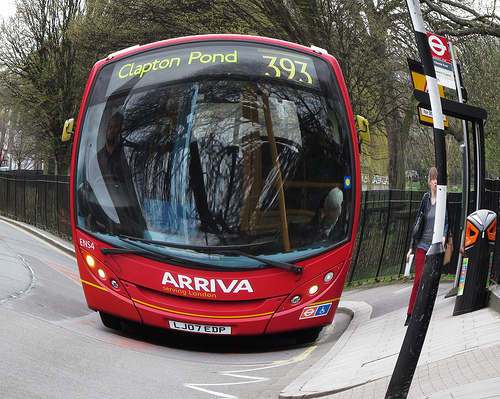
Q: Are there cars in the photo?
A: No, there are no cars.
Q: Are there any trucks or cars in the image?
A: No, there are no cars or trucks.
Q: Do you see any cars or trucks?
A: No, there are no cars or trucks.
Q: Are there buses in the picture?
A: Yes, there is a bus.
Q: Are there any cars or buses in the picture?
A: Yes, there is a bus.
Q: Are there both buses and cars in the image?
A: No, there is a bus but no cars.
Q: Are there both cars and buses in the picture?
A: No, there is a bus but no cars.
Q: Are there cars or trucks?
A: No, there are no cars or trucks.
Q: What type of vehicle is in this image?
A: The vehicle is a bus.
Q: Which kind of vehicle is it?
A: The vehicle is a bus.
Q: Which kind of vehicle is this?
A: That is a bus.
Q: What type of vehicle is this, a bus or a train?
A: That is a bus.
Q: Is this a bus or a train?
A: This is a bus.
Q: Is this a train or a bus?
A: This is a bus.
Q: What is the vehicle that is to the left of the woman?
A: The vehicle is a bus.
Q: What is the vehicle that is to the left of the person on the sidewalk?
A: The vehicle is a bus.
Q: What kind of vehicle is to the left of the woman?
A: The vehicle is a bus.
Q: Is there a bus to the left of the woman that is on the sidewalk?
A: Yes, there is a bus to the left of the woman.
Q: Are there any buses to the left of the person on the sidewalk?
A: Yes, there is a bus to the left of the woman.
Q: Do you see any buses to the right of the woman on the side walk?
A: No, the bus is to the left of the woman.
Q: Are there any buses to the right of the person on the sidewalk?
A: No, the bus is to the left of the woman.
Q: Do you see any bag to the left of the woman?
A: No, there is a bus to the left of the woman.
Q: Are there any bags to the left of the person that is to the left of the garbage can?
A: No, there is a bus to the left of the woman.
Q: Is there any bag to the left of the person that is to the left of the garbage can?
A: No, there is a bus to the left of the woman.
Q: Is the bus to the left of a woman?
A: Yes, the bus is to the left of a woman.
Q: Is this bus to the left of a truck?
A: No, the bus is to the left of a woman.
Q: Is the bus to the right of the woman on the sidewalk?
A: No, the bus is to the left of the woman.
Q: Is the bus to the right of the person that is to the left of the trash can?
A: No, the bus is to the left of the woman.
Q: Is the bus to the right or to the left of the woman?
A: The bus is to the left of the woman.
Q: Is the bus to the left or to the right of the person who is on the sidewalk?
A: The bus is to the left of the woman.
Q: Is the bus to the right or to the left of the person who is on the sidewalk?
A: The bus is to the left of the woman.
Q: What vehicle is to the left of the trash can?
A: The vehicle is a bus.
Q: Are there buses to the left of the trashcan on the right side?
A: Yes, there is a bus to the left of the garbage can.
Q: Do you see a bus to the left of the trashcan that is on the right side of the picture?
A: Yes, there is a bus to the left of the garbage can.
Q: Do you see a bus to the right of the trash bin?
A: No, the bus is to the left of the trash bin.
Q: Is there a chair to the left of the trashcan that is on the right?
A: No, there is a bus to the left of the trash can.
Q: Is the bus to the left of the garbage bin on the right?
A: Yes, the bus is to the left of the trash bin.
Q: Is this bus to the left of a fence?
A: No, the bus is to the left of the trash bin.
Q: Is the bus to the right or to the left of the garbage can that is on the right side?
A: The bus is to the left of the garbage bin.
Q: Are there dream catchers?
A: No, there are no dream catchers.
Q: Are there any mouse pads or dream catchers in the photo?
A: No, there are no dream catchers or mouse pads.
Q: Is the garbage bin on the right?
A: Yes, the garbage bin is on the right of the image.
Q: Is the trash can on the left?
A: No, the trash can is on the right of the image.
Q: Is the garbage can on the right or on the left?
A: The garbage can is on the right of the image.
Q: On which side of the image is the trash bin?
A: The trash bin is on the right of the image.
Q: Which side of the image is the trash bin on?
A: The trash bin is on the right of the image.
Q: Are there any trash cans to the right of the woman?
A: Yes, there is a trash can to the right of the woman.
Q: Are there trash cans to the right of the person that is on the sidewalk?
A: Yes, there is a trash can to the right of the woman.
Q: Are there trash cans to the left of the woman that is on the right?
A: No, the trash can is to the right of the woman.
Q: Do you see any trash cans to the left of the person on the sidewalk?
A: No, the trash can is to the right of the woman.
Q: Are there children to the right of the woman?
A: No, there is a trash can to the right of the woman.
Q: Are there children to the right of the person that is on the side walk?
A: No, there is a trash can to the right of the woman.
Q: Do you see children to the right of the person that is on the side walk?
A: No, there is a trash can to the right of the woman.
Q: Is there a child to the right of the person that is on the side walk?
A: No, there is a trash can to the right of the woman.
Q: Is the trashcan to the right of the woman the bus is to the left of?
A: Yes, the trashcan is to the right of the woman.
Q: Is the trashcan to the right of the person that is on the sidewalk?
A: Yes, the trashcan is to the right of the woman.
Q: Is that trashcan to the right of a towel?
A: No, the trashcan is to the right of the woman.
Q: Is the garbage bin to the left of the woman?
A: No, the garbage bin is to the right of the woman.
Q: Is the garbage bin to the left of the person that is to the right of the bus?
A: No, the garbage bin is to the right of the woman.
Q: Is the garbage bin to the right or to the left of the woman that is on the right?
A: The garbage bin is to the right of the woman.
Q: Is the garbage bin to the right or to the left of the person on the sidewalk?
A: The garbage bin is to the right of the woman.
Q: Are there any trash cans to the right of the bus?
A: Yes, there is a trash can to the right of the bus.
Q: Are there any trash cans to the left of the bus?
A: No, the trash can is to the right of the bus.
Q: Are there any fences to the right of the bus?
A: No, there is a trash can to the right of the bus.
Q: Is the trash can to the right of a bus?
A: Yes, the trash can is to the right of a bus.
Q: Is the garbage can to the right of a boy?
A: No, the garbage can is to the right of a bus.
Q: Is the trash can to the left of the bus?
A: No, the trash can is to the right of the bus.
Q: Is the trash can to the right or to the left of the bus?
A: The trash can is to the right of the bus.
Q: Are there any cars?
A: No, there are no cars.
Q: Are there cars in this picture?
A: No, there are no cars.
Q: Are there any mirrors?
A: Yes, there is a mirror.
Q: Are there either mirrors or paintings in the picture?
A: Yes, there is a mirror.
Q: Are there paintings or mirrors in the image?
A: Yes, there is a mirror.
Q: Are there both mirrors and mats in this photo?
A: No, there is a mirror but no mats.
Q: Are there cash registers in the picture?
A: No, there are no cash registers.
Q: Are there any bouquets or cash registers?
A: No, there are no cash registers or bouquets.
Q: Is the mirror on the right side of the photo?
A: Yes, the mirror is on the right of the image.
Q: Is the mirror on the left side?
A: No, the mirror is on the right of the image.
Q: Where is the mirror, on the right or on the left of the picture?
A: The mirror is on the right of the image.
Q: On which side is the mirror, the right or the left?
A: The mirror is on the right of the image.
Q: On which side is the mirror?
A: The mirror is on the right of the image.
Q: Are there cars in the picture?
A: No, there are no cars.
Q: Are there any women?
A: Yes, there is a woman.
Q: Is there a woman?
A: Yes, there is a woman.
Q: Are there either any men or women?
A: Yes, there is a woman.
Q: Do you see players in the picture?
A: No, there are no players.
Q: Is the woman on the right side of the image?
A: Yes, the woman is on the right of the image.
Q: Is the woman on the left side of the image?
A: No, the woman is on the right of the image.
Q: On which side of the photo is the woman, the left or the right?
A: The woman is on the right of the image.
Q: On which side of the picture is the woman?
A: The woman is on the right of the image.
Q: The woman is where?
A: The woman is on the side walk.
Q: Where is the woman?
A: The woman is on the side walk.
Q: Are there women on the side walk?
A: Yes, there is a woman on the side walk.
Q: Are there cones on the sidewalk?
A: No, there is a woman on the sidewalk.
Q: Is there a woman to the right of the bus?
A: Yes, there is a woman to the right of the bus.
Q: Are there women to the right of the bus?
A: Yes, there is a woman to the right of the bus.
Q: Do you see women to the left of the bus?
A: No, the woman is to the right of the bus.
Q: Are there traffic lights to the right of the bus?
A: No, there is a woman to the right of the bus.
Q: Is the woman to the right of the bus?
A: Yes, the woman is to the right of the bus.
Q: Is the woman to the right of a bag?
A: No, the woman is to the right of the bus.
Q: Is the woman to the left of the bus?
A: No, the woman is to the right of the bus.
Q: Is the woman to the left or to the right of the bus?
A: The woman is to the right of the bus.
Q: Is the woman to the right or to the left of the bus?
A: The woman is to the right of the bus.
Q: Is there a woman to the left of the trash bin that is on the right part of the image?
A: Yes, there is a woman to the left of the garbage bin.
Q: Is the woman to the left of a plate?
A: No, the woman is to the left of the trash bin.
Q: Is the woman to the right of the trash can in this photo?
A: No, the woman is to the left of the trash can.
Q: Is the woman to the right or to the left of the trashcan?
A: The woman is to the left of the trashcan.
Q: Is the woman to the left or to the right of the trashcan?
A: The woman is to the left of the trashcan.